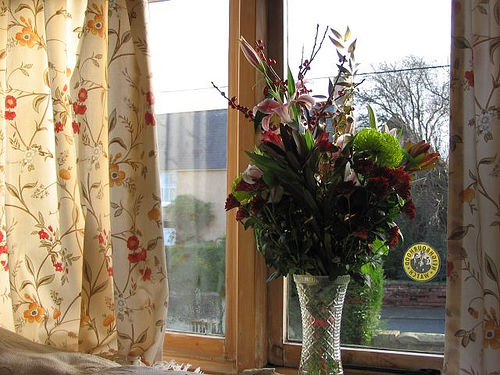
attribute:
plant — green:
[210, 22, 440, 374]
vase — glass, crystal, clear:
[293, 274, 352, 374]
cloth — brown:
[1, 324, 208, 374]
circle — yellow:
[402, 243, 440, 282]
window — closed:
[144, 1, 229, 338]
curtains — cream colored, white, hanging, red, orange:
[0, 0, 168, 366]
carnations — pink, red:
[224, 192, 240, 209]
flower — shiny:
[352, 127, 403, 166]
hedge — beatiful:
[161, 191, 227, 315]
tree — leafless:
[356, 51, 449, 282]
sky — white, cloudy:
[149, 1, 451, 164]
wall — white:
[235, 0, 258, 375]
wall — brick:
[380, 278, 446, 308]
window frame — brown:
[256, 0, 464, 375]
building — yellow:
[158, 169, 228, 249]